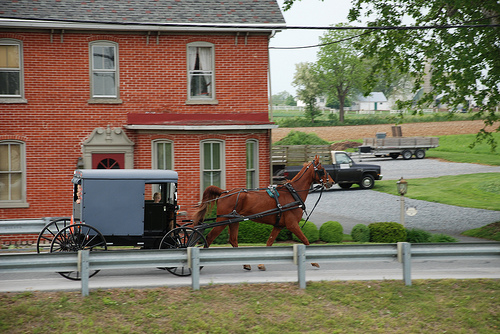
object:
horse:
[193, 155, 336, 270]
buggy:
[38, 155, 337, 281]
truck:
[271, 152, 383, 190]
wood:
[272, 144, 333, 166]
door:
[92, 151, 126, 168]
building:
[0, 1, 288, 248]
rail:
[0, 242, 499, 297]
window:
[185, 39, 218, 106]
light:
[396, 177, 410, 195]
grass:
[375, 173, 500, 214]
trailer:
[355, 137, 438, 160]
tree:
[347, 3, 500, 155]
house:
[355, 92, 388, 114]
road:
[0, 252, 500, 292]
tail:
[190, 186, 223, 227]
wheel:
[160, 225, 210, 277]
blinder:
[318, 169, 324, 177]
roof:
[0, 1, 286, 26]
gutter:
[0, 18, 287, 33]